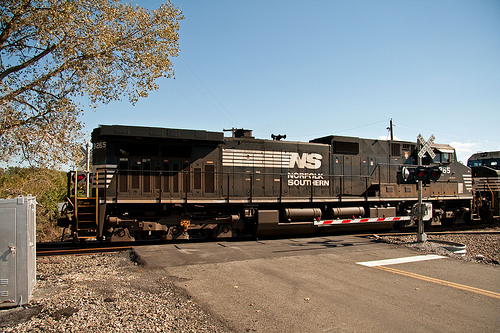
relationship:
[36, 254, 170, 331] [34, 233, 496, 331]
rocks in ground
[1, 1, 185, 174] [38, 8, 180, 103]
tree has leaves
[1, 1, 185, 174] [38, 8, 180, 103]
tree has branches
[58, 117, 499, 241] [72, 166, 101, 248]
train has ladder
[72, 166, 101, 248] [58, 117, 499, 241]
letters ns on train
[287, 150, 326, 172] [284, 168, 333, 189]
ns stands for norfolk southern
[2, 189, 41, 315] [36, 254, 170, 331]
box on gravel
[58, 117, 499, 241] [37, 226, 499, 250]
train on track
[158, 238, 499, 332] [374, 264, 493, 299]
street has solid lines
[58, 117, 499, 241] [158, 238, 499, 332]
train crossing over paved road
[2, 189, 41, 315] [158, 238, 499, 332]
box on side road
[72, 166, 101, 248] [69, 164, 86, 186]
ladder in front of light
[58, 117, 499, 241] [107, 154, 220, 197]
train has panels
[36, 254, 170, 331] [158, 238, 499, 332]
gravel on side road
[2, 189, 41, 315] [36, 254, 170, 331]
box in gravel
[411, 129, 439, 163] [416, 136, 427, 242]
sign on pole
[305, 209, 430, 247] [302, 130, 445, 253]
gate for road crossing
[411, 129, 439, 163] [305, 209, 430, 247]
sign for crossing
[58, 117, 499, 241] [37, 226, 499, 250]
locomotive on railroad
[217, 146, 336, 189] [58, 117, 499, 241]
logo on locomotive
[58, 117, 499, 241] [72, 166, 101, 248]
locomotive has ladder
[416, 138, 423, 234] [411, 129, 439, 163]
pole for signs